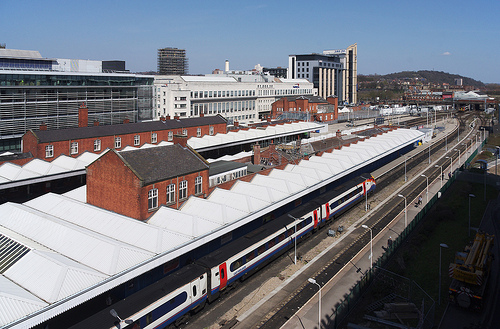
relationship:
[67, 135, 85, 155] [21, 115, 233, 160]
window with building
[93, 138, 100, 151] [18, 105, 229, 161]
window on building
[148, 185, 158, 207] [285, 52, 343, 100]
window on building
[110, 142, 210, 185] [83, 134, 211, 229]
roof on building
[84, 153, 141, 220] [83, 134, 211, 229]
wall on side of a building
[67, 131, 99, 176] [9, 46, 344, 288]
window on building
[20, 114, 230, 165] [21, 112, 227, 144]
building with roof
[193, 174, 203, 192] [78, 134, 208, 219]
window on a building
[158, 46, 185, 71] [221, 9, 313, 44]
building is against sky